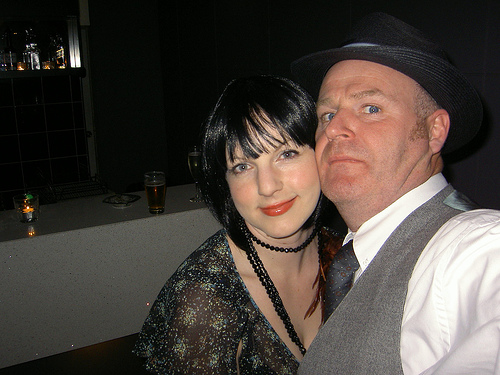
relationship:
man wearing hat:
[300, 64, 499, 372] [287, 4, 494, 164]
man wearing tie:
[300, 64, 499, 372] [314, 241, 359, 323]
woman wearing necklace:
[131, 68, 345, 370] [239, 221, 319, 356]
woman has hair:
[131, 68, 345, 370] [194, 67, 320, 250]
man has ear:
[300, 64, 499, 372] [423, 110, 451, 155]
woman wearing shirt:
[131, 68, 345, 370] [135, 226, 302, 374]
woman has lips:
[131, 68, 345, 370] [259, 196, 299, 218]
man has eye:
[300, 64, 499, 372] [358, 104, 382, 116]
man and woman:
[300, 64, 499, 372] [131, 68, 345, 370]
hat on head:
[287, 4, 494, 164] [311, 61, 446, 234]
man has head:
[300, 64, 499, 372] [311, 61, 446, 234]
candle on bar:
[9, 189, 40, 224] [1, 182, 224, 367]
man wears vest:
[300, 64, 499, 372] [295, 186, 476, 373]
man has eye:
[300, 64, 499, 372] [317, 110, 336, 122]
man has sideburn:
[300, 64, 499, 372] [409, 117, 429, 141]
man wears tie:
[300, 64, 499, 372] [314, 241, 359, 323]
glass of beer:
[141, 168, 169, 218] [145, 183, 168, 208]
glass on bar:
[141, 168, 169, 218] [1, 182, 224, 367]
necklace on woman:
[239, 221, 319, 356] [131, 68, 345, 370]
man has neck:
[300, 64, 499, 372] [330, 175, 456, 234]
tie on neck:
[314, 241, 359, 323] [330, 175, 456, 234]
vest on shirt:
[295, 186, 476, 373] [342, 170, 498, 374]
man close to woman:
[300, 64, 499, 372] [131, 68, 345, 370]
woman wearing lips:
[131, 68, 345, 370] [259, 196, 299, 218]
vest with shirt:
[295, 186, 476, 373] [342, 170, 498, 374]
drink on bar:
[183, 152, 206, 203] [1, 182, 224, 367]